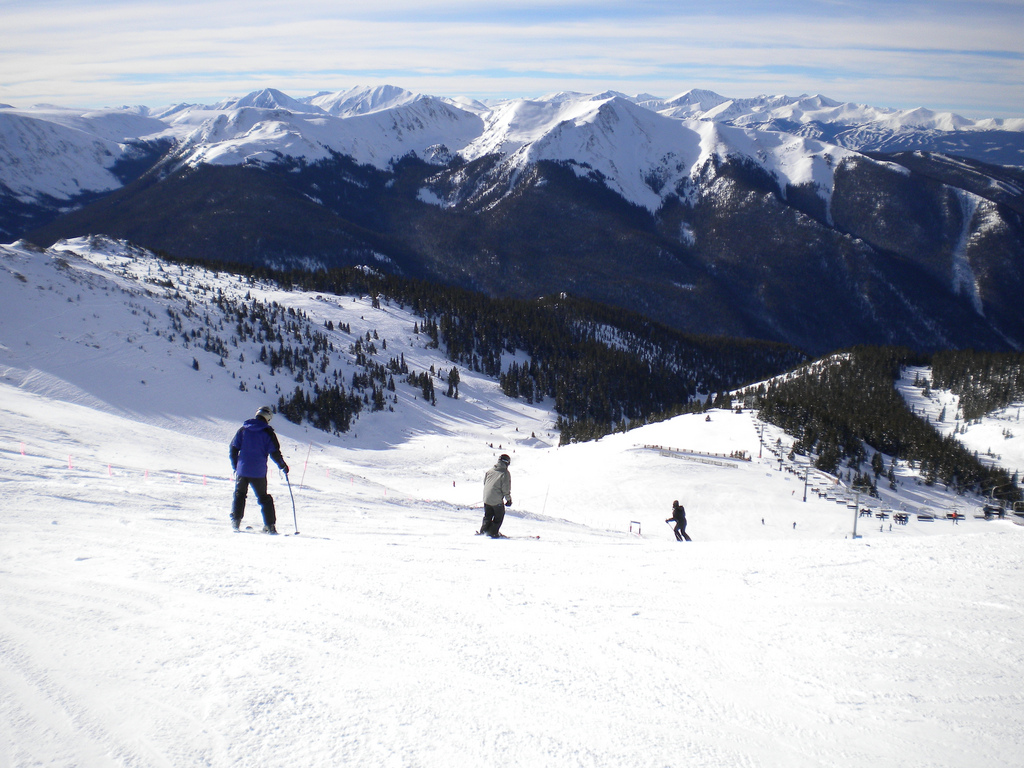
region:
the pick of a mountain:
[571, 85, 645, 143]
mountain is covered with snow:
[12, 68, 1006, 261]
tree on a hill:
[436, 355, 476, 414]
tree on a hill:
[322, 381, 370, 442]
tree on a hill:
[152, 284, 194, 343]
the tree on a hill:
[250, 330, 279, 378]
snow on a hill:
[8, 257, 737, 766]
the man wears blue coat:
[209, 393, 308, 546]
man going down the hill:
[204, 371, 361, 559]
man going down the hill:
[464, 425, 579, 566]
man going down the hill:
[619, 483, 695, 567]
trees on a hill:
[711, 346, 1015, 524]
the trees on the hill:
[286, 365, 376, 442]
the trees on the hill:
[403, 354, 464, 403]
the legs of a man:
[212, 448, 304, 550]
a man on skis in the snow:
[199, 318, 365, 572]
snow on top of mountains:
[109, 21, 691, 418]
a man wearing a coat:
[464, 436, 557, 519]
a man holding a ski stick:
[256, 429, 339, 570]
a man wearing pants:
[451, 397, 570, 550]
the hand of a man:
[274, 438, 319, 493]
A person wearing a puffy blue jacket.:
[224, 404, 304, 541]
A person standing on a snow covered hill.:
[467, 452, 543, 548]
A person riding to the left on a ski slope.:
[663, 499, 698, 548]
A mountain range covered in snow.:
[5, 76, 1021, 454]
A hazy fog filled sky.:
[2, 0, 1021, 119]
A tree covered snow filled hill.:
[6, 345, 1021, 523]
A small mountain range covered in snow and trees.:
[2, 229, 1021, 534]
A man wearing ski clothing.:
[223, 405, 303, 539]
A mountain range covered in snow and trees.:
[0, 89, 1022, 362]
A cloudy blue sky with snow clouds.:
[0, 0, 1021, 114]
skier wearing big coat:
[221, 403, 301, 543]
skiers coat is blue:
[216, 412, 292, 493]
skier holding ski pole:
[281, 460, 308, 536]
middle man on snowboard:
[472, 437, 523, 543]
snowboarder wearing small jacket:
[475, 454, 515, 513]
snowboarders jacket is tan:
[480, 460, 512, 512]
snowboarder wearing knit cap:
[494, 444, 511, 474]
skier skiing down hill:
[661, 492, 694, 557]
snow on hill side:
[7, 235, 1020, 767]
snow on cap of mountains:
[0, 85, 1018, 250]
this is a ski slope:
[163, 199, 853, 713]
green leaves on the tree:
[860, 410, 918, 445]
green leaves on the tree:
[814, 423, 834, 452]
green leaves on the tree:
[546, 392, 567, 409]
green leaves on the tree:
[599, 386, 625, 399]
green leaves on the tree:
[642, 364, 668, 385]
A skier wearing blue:
[226, 405, 290, 538]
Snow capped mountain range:
[0, 81, 1021, 398]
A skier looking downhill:
[476, 453, 514, 540]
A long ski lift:
[747, 400, 1019, 536]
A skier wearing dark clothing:
[664, 497, 690, 548]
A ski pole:
[283, 475, 302, 534]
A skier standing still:
[231, 403, 290, 533]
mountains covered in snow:
[11, 80, 1023, 539]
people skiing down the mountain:
[220, 397, 698, 557]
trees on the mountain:
[219, 252, 1010, 525]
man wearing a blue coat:
[230, 398, 300, 547]